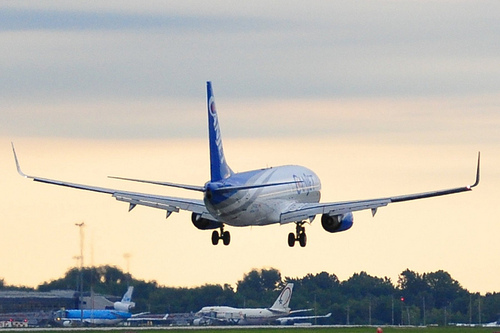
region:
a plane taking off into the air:
[10, 74, 480, 247]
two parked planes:
[50, 283, 304, 330]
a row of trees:
[324, 277, 494, 327]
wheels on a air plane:
[280, 227, 312, 248]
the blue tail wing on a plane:
[197, 77, 227, 194]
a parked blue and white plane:
[45, 282, 145, 328]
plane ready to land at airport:
[6, 66, 494, 326]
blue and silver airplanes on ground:
[49, 283, 330, 328]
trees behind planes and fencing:
[43, 259, 494, 324]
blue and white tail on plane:
[203, 73, 229, 184]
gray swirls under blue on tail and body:
[200, 78, 281, 220]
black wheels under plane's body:
[206, 206, 311, 249]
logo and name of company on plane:
[287, 160, 323, 202]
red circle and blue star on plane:
[274, 279, 294, 309]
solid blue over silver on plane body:
[44, 297, 134, 327]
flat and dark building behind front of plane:
[2, 286, 79, 328]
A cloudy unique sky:
[189, 62, 424, 121]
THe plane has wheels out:
[165, 217, 341, 286]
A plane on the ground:
[154, 291, 325, 330]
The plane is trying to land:
[143, 135, 492, 228]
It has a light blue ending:
[180, 155, 285, 219]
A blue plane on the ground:
[26, 292, 160, 332]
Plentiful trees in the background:
[322, 269, 471, 330]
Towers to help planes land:
[56, 218, 120, 288]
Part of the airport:
[11, 280, 92, 315]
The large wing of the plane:
[6, 141, 207, 222]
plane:
[29, 73, 493, 243]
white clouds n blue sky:
[32, 21, 70, 61]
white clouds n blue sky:
[429, 16, 460, 57]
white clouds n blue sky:
[343, 38, 391, 75]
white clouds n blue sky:
[369, 96, 417, 121]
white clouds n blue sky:
[96, 83, 138, 123]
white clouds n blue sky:
[245, 58, 300, 98]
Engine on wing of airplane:
[317, 203, 362, 236]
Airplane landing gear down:
[208, 223, 313, 258]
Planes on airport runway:
[36, 276, 320, 328]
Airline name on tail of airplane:
[202, 89, 229, 186]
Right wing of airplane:
[283, 143, 495, 217]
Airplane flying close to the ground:
[5, 63, 499, 255]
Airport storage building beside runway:
[7, 277, 83, 322]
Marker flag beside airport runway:
[391, 291, 408, 321]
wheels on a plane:
[196, 226, 315, 253]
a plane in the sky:
[2, 77, 498, 257]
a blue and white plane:
[36, 296, 167, 331]